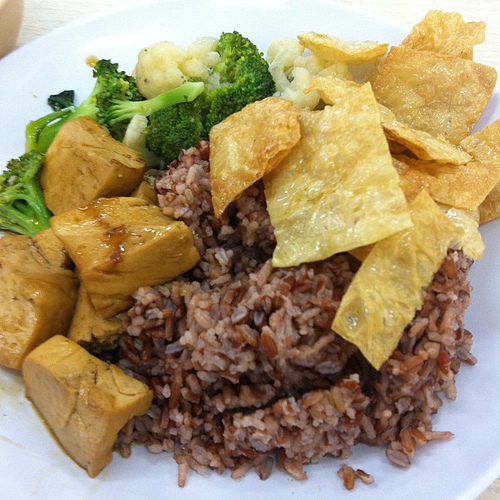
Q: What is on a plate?
A: Rice.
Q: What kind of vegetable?
A: Cauliflower.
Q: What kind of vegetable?
A: Broccoli.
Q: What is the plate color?
A: White.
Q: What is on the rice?
A: Chips.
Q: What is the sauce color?
A: Brown.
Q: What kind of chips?
A: Crispy.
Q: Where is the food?
A: Plate.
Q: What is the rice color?
A: Brown.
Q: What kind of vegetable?
A: Broccoli.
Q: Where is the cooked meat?
A: On a white plate.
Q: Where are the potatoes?
A: With the meat on a white plate.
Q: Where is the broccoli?
A: On a white plate with meat, rice and potatoes.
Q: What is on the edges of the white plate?
A: Nothing.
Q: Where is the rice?
A: On the dinner plate with the meat and broccoli.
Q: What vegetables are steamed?
A: Cauliflower and broccoli.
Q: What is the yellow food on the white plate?
A: Crunchy fried tortilla squares.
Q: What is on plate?
A: Food.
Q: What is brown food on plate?
A: Rice.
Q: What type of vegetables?
A: Broccoli.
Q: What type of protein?
A: Meat.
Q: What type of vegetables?
A: Broccoli.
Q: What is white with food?
A: Plate.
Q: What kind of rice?
A: Brown.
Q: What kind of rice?
A: Brown.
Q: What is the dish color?
A: White.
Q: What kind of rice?
A: Brown.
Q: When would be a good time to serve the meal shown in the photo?
A: Lunchtime.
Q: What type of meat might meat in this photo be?
A: Pork.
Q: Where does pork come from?
A: Pigs.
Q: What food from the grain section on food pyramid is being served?
A: Rice.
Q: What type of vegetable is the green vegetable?
A: Broccoli.